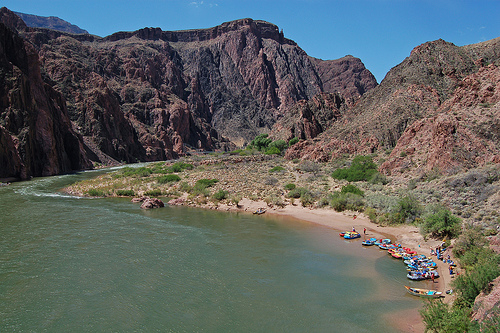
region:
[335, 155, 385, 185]
Large green bush near hill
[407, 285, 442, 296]
Canoe sitting on beach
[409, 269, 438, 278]
Raft sitting on beach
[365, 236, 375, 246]
Bright blue jetski on beach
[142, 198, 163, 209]
Rock sticking out of water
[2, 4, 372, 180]
Large rocky cliff near water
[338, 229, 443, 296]
Group of water vehicles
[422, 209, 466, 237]
Fat bush near beach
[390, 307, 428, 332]
Patch of sand under shallow water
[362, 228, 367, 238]
Person standing near boats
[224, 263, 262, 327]
part of a water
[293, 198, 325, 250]
edge of a shore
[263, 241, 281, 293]
part of a water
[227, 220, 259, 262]
part of a water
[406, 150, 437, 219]
part of a ground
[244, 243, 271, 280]
part fo a water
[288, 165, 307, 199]
part of a plant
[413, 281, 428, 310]
part of a vboat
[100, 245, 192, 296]
water next to the boats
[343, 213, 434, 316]
boats next to the beach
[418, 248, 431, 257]
sand next to the boats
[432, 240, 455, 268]
people on the beach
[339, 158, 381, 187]
green stuff behind people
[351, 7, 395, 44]
blue sky above the mountain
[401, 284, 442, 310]
one boat next to many others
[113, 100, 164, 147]
rocks next to the water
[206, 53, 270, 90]
rocks on the mountain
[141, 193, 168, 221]
rock in the water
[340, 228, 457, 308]
Boats on the water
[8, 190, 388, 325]
Ocean water by sand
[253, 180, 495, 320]
Tan sand on a beach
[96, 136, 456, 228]
Bushes around the beach area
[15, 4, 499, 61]
Really blue sky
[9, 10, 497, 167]
Mountain that is rocky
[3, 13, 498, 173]
Mountain is a dark brown color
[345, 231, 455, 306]
The boats are very colorful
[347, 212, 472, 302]
People are on the sand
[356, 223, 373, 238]
A person with a red shirt is standing up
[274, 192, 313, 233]
edge of a shore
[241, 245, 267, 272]
part of a water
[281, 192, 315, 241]
edge of a shore